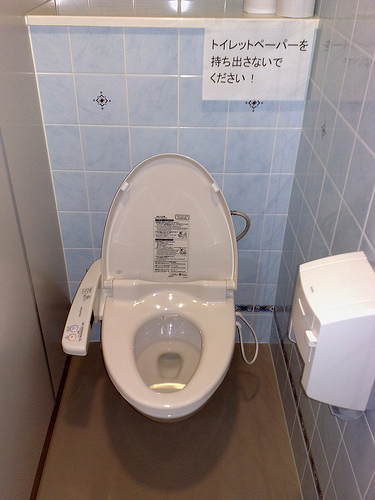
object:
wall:
[26, 26, 316, 344]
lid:
[100, 153, 239, 290]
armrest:
[60, 259, 100, 355]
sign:
[203, 18, 320, 103]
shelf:
[24, 1, 319, 25]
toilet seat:
[101, 286, 240, 424]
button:
[67, 333, 76, 339]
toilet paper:
[277, 0, 318, 20]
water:
[136, 339, 198, 392]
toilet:
[60, 154, 239, 424]